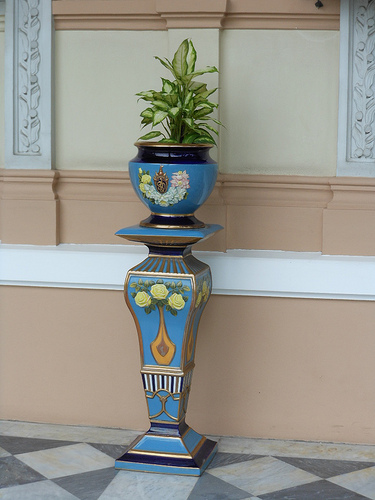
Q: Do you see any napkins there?
A: No, there are no napkins.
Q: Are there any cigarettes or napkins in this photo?
A: No, there are no napkins or cigarettes.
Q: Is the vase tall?
A: Yes, the vase is tall.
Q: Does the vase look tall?
A: Yes, the vase is tall.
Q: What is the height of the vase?
A: The vase is tall.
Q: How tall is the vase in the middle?
A: The vase is tall.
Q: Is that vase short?
A: No, the vase is tall.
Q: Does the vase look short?
A: No, the vase is tall.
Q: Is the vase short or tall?
A: The vase is tall.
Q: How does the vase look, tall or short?
A: The vase is tall.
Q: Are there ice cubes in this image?
A: No, there are no ice cubes.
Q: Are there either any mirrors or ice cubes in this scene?
A: No, there are no ice cubes or mirrors.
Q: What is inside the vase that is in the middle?
A: The plant is inside the vase.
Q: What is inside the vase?
A: The plant is inside the vase.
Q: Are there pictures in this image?
A: No, there are no pictures.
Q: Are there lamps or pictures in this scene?
A: No, there are no pictures or lamps.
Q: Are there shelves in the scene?
A: No, there are no shelves.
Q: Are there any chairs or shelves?
A: No, there are no shelves or chairs.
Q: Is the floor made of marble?
A: Yes, the floor is made of marble.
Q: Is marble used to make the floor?
A: Yes, the floor is made of marble.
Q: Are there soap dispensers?
A: No, there are no soap dispensers.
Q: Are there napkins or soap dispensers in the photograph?
A: No, there are no soap dispensers or napkins.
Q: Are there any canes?
A: No, there are no canes.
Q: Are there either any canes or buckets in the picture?
A: No, there are no canes or buckets.